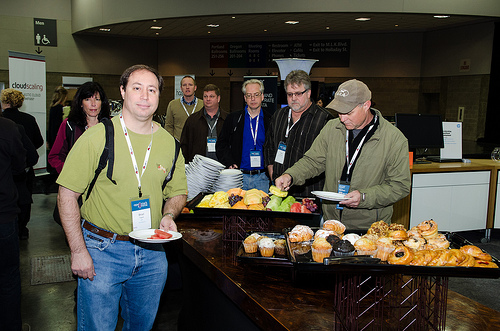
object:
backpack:
[52, 117, 180, 226]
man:
[53, 64, 188, 331]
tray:
[184, 192, 322, 221]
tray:
[284, 230, 499, 272]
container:
[181, 191, 321, 229]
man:
[261, 69, 335, 197]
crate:
[334, 273, 447, 331]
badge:
[119, 112, 153, 231]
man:
[273, 78, 412, 230]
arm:
[55, 122, 104, 253]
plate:
[235, 230, 499, 278]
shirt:
[55, 114, 188, 236]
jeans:
[76, 218, 170, 331]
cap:
[325, 78, 372, 113]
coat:
[281, 108, 411, 230]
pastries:
[242, 236, 259, 254]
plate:
[311, 190, 351, 201]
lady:
[48, 81, 112, 174]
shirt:
[48, 117, 112, 173]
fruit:
[303, 199, 318, 212]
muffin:
[310, 240, 332, 263]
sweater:
[164, 97, 203, 141]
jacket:
[216, 105, 277, 167]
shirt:
[263, 102, 335, 197]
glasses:
[287, 89, 309, 97]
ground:
[0, 194, 75, 331]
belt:
[81, 220, 129, 241]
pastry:
[257, 238, 275, 257]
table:
[171, 222, 500, 331]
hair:
[119, 64, 165, 93]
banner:
[7, 57, 51, 176]